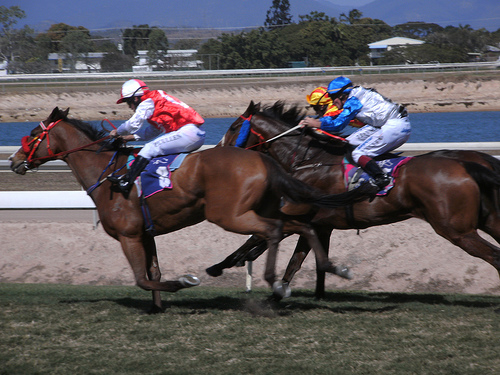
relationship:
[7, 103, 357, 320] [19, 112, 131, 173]
horse has briddles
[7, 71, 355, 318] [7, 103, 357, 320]
man riding horse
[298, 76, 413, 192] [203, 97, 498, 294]
man riding horse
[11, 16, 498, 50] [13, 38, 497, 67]
power lines above trees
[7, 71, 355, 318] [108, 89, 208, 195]
man wearing red and white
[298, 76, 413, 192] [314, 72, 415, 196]
man wearing blue and white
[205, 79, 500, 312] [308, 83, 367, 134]
man wearing red and gold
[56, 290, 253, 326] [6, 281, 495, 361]
shadow on ground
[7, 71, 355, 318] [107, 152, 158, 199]
man wearing boots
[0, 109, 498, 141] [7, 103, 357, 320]
water behind horse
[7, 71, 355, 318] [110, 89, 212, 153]
man wearing shirt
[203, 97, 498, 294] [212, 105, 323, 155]
horse with briddles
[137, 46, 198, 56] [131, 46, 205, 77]
roof of house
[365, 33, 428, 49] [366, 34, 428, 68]
roof of house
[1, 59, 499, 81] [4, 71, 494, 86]
guard rail along road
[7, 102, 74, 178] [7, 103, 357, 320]
head of horse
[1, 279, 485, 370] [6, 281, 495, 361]
grass on track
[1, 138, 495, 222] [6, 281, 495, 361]
fence on race track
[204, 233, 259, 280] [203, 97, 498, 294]
leg of horse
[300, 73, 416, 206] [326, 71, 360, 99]
man wearing helmet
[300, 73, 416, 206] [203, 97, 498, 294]
man riding horse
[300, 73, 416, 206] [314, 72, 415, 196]
man wearing blue and white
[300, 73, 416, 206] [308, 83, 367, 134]
man wearing yellow and red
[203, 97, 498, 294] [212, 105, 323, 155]
horse has briddles